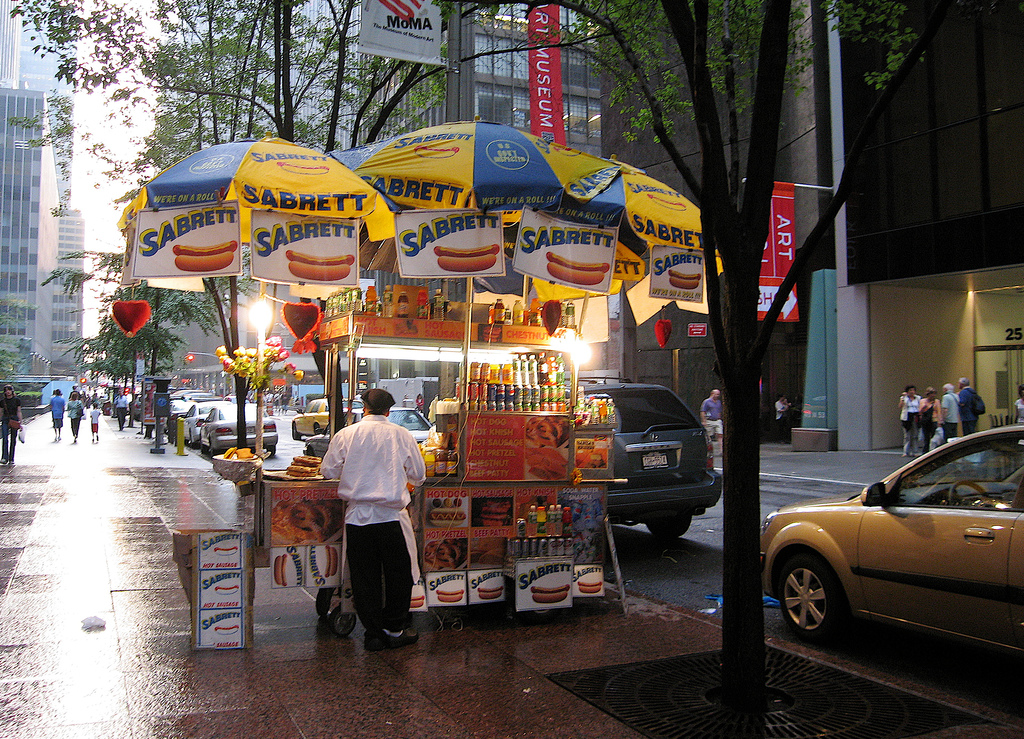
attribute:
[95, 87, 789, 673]
stand — blue and yellow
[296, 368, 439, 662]
working man — wearing white apron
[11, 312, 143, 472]
people — walking in the distance